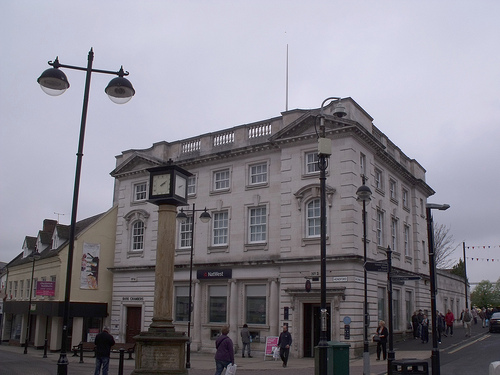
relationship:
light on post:
[37, 67, 70, 98] [56, 48, 95, 374]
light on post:
[103, 76, 136, 105] [56, 48, 95, 374]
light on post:
[176, 212, 188, 226] [184, 204, 196, 368]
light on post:
[200, 212, 212, 224] [184, 204, 196, 368]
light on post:
[331, 101, 350, 121] [313, 97, 340, 374]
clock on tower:
[147, 157, 193, 208] [129, 205, 192, 374]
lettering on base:
[144, 345, 179, 367] [131, 329, 193, 374]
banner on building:
[78, 241, 103, 289] [1, 203, 120, 356]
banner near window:
[78, 241, 103, 289] [129, 216, 146, 253]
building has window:
[106, 96, 435, 360] [129, 216, 146, 253]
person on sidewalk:
[241, 323, 254, 361] [2, 315, 498, 374]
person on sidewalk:
[278, 323, 293, 368] [2, 315, 498, 374]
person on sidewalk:
[374, 321, 389, 363] [2, 315, 498, 374]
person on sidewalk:
[462, 307, 475, 340] [2, 315, 498, 374]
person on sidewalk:
[445, 309, 456, 337] [2, 315, 498, 374]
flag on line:
[466, 246, 470, 250] [464, 243, 499, 250]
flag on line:
[472, 246, 473, 247] [464, 243, 499, 250]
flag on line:
[477, 245, 479, 246] [464, 243, 499, 250]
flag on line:
[488, 244, 489, 247] [464, 243, 499, 250]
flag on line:
[494, 244, 495, 247] [464, 243, 499, 250]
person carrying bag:
[374, 321, 389, 363] [373, 333, 383, 342]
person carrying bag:
[215, 326, 239, 374] [226, 363, 238, 375]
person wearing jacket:
[215, 326, 239, 374] [215, 334, 237, 367]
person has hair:
[215, 326, 239, 374] [221, 323, 231, 335]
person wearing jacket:
[278, 323, 293, 368] [276, 330, 293, 350]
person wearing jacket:
[94, 326, 116, 374] [93, 331, 116, 358]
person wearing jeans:
[215, 326, 239, 374] [215, 359, 236, 374]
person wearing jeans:
[94, 326, 116, 374] [94, 354, 110, 374]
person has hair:
[94, 326, 116, 374] [102, 324, 111, 332]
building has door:
[106, 96, 435, 360] [310, 305, 330, 357]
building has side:
[106, 96, 435, 360] [352, 97, 440, 360]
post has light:
[56, 48, 95, 374] [37, 67, 70, 98]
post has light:
[56, 48, 95, 374] [103, 76, 136, 105]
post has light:
[313, 97, 340, 374] [331, 101, 350, 121]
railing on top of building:
[168, 115, 282, 163] [106, 96, 435, 360]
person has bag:
[215, 326, 239, 374] [226, 363, 238, 375]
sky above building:
[1, 1, 500, 306] [106, 96, 435, 360]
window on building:
[174, 283, 192, 320] [106, 96, 435, 360]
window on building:
[208, 286, 228, 323] [106, 96, 435, 360]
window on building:
[244, 282, 267, 325] [106, 96, 435, 360]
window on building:
[378, 286, 387, 323] [106, 96, 435, 360]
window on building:
[392, 288, 401, 329] [106, 96, 435, 360]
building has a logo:
[106, 96, 435, 360] [197, 267, 234, 280]